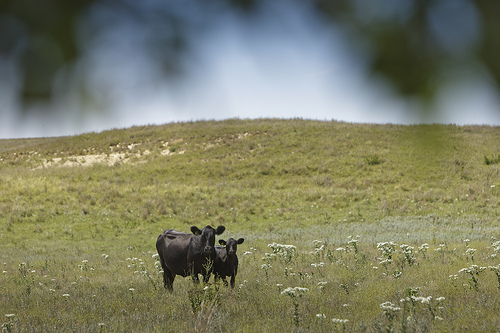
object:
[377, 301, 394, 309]
flowers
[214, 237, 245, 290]
cow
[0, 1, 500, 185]
vegetation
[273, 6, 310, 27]
blue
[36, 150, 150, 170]
dirt patch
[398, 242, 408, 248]
flowers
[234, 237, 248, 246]
right ear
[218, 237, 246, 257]
head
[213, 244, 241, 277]
body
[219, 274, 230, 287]
legs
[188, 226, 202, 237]
left ear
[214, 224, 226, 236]
right ear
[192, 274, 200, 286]
legs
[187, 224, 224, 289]
front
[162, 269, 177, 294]
legs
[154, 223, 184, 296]
back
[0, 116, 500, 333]
field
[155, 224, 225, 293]
cows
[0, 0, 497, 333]
camera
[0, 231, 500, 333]
plant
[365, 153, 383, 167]
brush